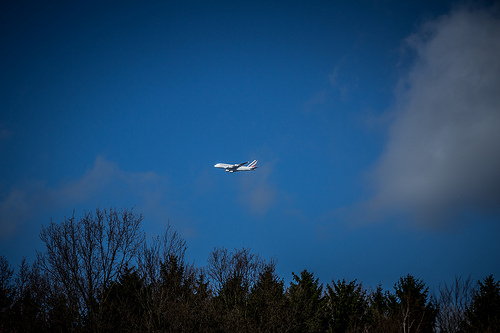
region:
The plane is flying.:
[210, 158, 263, 175]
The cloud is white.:
[405, 62, 489, 200]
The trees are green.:
[238, 272, 325, 322]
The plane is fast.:
[210, 151, 269, 182]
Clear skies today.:
[131, 30, 239, 97]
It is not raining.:
[115, 68, 232, 122]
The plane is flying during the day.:
[176, 41, 325, 106]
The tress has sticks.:
[65, 221, 125, 273]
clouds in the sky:
[407, 7, 498, 186]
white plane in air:
[208, 156, 268, 172]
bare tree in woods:
[56, 215, 112, 326]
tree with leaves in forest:
[247, 269, 295, 330]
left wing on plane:
[230, 157, 247, 169]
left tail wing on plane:
[246, 153, 257, 168]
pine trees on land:
[255, 273, 283, 328]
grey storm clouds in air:
[60, 157, 180, 208]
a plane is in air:
[203, 128, 305, 227]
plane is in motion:
[208, 129, 292, 215]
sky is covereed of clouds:
[381, 118, 461, 250]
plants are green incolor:
[110, 227, 202, 292]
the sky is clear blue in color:
[249, 36, 351, 161]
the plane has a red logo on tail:
[238, 142, 263, 172]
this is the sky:
[104, 43, 207, 143]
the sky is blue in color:
[113, 48, 209, 115]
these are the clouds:
[401, 55, 461, 189]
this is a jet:
[201, 154, 267, 181]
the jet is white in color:
[218, 163, 227, 166]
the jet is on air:
[211, 149, 263, 176]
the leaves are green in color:
[293, 273, 323, 310]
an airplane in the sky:
[210, 155, 260, 170]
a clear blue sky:
[0, 0, 495, 315]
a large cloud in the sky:
[355, 5, 490, 235]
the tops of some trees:
[0, 205, 495, 325]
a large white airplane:
[211, 149, 263, 176]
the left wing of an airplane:
[231, 158, 248, 170]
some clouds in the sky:
[0, 3, 497, 238]